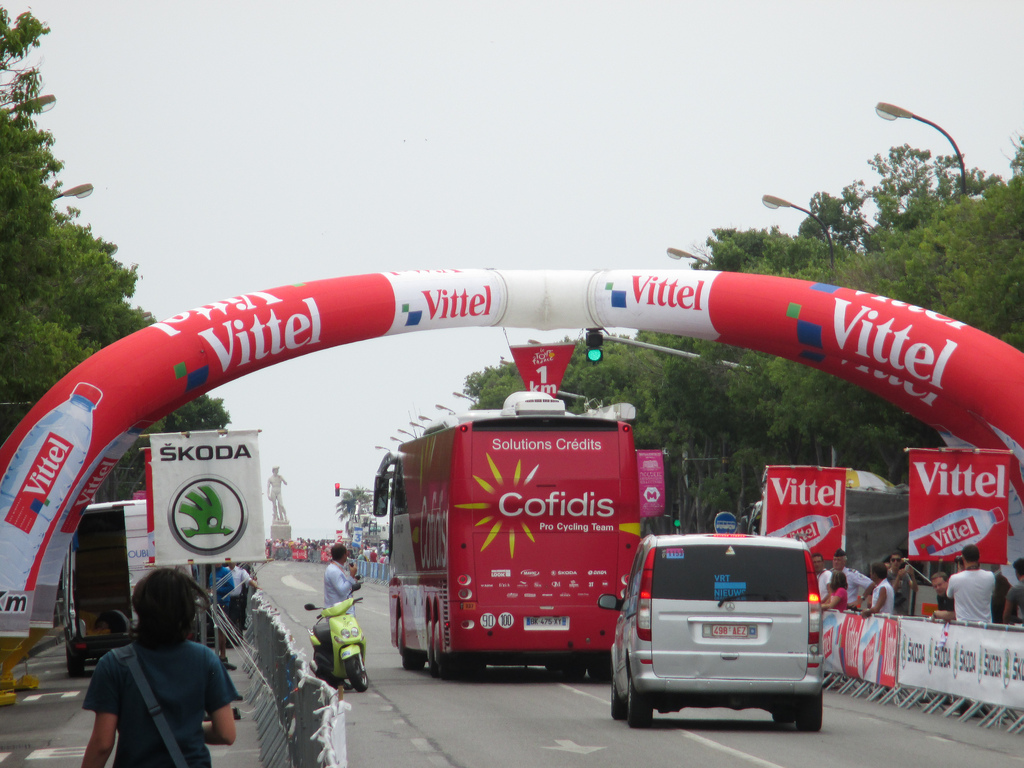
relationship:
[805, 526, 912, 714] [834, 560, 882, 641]
man wearing shirt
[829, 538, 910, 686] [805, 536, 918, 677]
man wearing shirt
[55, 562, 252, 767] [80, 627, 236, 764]
person wearing shirt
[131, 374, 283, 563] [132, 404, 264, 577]
sign with business logo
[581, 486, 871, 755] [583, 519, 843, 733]
rear end of suv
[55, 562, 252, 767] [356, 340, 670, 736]
person by bus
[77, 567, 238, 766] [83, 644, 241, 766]
person in a shirt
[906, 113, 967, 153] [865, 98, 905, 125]
post of a street lamp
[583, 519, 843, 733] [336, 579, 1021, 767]
suv driving down street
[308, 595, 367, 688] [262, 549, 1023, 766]
motorcycle on side of street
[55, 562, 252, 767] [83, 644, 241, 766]
person with shirt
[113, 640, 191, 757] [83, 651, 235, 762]
strap on back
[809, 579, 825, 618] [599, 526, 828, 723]
light on back of car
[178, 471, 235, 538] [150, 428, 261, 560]
logo on sign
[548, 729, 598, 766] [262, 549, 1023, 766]
arrow on street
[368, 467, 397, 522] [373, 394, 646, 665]
mirror on bus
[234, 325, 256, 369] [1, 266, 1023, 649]
letter on sign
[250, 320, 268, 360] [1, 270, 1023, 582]
letter on sign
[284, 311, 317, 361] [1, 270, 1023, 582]
letter on sign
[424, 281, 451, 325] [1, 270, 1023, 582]
letter on sign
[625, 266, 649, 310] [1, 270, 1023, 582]
letter on sign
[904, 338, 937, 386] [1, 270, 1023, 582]
letter on sign